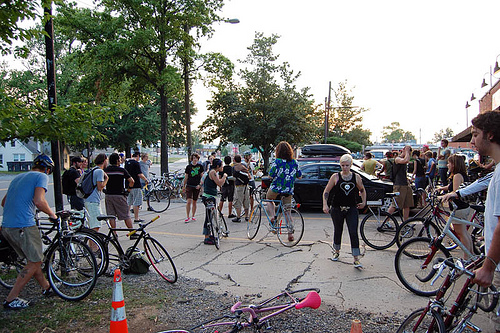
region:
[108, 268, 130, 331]
the orange cone with reflectors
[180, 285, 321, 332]
the pink bike on its side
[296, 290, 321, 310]
the bright pink bike seat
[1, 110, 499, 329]
the large group of people and their bikes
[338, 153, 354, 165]
the short light blonde hair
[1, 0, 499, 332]
the trees near the large group of people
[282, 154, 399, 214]
the car is black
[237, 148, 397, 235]
the car is black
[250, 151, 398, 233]
the car is black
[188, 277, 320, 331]
bike on the ground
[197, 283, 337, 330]
bike on the ground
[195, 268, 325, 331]
bike on the ground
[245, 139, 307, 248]
person standing next to bicycle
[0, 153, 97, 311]
person standing next to bicycle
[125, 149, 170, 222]
person standing next to bicycle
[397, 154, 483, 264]
person standing next to bicycle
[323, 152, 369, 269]
woman with blonde hair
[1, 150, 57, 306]
person wearing light blue shirt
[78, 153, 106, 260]
person wearing light blue shirt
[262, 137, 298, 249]
person wearing blue shirt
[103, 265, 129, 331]
orange and silver traffic cone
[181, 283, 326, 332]
pink bicycle with black tires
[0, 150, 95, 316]
man holding onto a bicycle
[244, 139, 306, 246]
woman riding a bicycle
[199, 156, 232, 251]
bicycle leaning against a woman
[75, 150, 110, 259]
man wearing a backpack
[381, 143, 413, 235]
man wearing brown shorts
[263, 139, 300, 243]
woman wearing blue floral shirt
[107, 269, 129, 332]
Orange and silver caution cone.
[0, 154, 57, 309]
A man in a helmet and blue shirt.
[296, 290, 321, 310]
Pink seat on a bike.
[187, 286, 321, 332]
A pink bike with pink sink.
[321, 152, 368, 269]
A blonde woman in black tank top and capris.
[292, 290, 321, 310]
A dark pink bicycle seat.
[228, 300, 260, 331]
Pink bike handlebars.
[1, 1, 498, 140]
White sky above.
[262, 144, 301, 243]
A person in a floral white and blue shirt with shoulder length brown hair.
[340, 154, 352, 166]
White pixie haircut on a woman's head.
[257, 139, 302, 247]
person at bike rally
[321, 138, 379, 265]
person at bike rally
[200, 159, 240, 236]
person at bike rally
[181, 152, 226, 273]
person at bike rally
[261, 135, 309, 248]
A person is standing up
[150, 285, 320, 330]
the bike is pink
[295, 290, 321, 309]
the seat is pink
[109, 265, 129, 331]
the cone is orange and gray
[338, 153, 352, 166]
the hair is blonde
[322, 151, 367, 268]
the hair has blond hair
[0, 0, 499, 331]
the trees under the bright sky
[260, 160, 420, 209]
the car is black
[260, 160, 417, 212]
the car is parked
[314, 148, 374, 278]
Woman wearing shirt with no sleeves walking on sidewalk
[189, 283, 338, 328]
Bike laying on the ground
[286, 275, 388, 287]
Crack in the pavement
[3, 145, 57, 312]
Man wearing shirt with short sleeves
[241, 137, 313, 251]
Person sitting on a bike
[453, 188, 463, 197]
Watch on left wrist of a person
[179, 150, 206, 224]
Person wearing a pair of shorts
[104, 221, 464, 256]
Line painted on a sidewalk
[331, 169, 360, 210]
black tank top with white heart